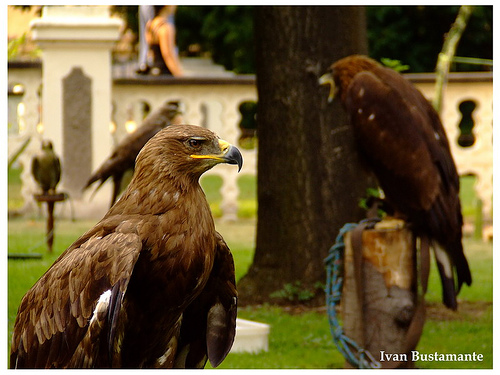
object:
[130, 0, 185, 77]
woman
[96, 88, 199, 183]
bird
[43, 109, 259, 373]
falcon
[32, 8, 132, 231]
pillar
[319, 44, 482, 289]
bird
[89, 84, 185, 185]
bird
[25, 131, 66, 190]
bird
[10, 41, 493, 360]
pen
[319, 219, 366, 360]
cord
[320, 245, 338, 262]
knot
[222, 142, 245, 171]
beak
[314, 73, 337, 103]
mouth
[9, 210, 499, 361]
grass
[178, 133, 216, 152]
eye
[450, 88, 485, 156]
design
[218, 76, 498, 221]
fence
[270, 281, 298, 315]
branch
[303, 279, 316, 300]
branch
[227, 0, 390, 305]
tree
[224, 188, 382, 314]
bottom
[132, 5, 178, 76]
girl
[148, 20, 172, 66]
shirt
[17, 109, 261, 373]
bird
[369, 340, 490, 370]
watermark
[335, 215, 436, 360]
stump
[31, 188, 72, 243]
stand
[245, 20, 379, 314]
tree trunk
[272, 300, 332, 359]
grass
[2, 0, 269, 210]
wall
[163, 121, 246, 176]
bird's peak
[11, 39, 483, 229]
building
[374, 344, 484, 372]
name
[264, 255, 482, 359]
grass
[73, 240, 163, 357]
white spot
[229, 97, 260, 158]
opening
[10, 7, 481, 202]
white structure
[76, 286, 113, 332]
white feather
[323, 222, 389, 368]
blue cord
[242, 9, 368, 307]
large/tree trunk